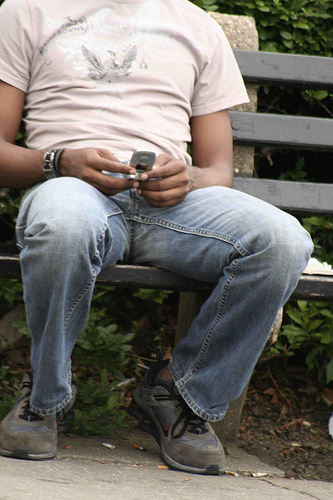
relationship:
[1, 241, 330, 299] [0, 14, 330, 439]
board on bench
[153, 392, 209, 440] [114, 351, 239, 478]
laces on shoe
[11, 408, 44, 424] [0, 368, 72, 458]
laces in a shoe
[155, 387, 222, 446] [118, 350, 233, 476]
laces in a shoe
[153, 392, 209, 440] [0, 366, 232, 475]
laces in a shoe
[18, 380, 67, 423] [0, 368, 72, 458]
laces in a shoe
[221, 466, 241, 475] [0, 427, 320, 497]
but on ground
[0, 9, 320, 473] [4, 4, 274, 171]
man wearing a shirt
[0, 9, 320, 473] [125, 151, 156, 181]
man holding cell phone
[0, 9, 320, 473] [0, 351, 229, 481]
man wearing shoes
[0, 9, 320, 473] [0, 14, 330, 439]
man sitting on a bench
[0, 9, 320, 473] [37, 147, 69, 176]
man wearing a bracelet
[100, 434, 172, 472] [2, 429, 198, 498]
butt on ground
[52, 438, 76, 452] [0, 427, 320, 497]
butt on ground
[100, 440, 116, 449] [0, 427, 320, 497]
butt on ground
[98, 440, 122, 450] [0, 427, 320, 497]
butt on ground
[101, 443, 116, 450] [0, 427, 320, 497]
butt on ground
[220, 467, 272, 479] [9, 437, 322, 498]
butt on ground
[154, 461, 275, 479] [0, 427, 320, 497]
butt on ground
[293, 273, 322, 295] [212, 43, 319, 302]
board on bench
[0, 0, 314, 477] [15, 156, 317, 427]
man wearing jeans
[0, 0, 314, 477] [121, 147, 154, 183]
man using phone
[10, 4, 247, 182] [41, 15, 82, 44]
shirt has letters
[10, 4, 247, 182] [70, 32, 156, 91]
shirt has pictures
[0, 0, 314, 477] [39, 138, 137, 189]
man has a hand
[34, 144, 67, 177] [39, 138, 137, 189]
wristband on hand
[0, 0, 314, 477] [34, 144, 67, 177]
man wears a wristband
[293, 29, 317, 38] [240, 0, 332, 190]
leaves are on plant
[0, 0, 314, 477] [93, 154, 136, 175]
man has a finger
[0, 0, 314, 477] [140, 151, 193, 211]
man has a hand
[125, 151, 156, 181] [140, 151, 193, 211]
cell phone in hand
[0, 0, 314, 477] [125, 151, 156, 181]
man holding cell phone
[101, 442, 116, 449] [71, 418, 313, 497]
butt on ground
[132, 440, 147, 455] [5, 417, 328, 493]
cigarette butt on ground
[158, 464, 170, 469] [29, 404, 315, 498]
butt on ground